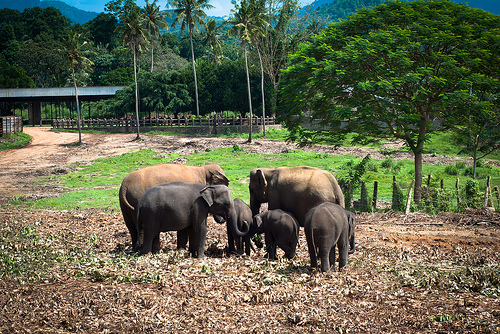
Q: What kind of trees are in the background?
A: Palm.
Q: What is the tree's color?
A: Green.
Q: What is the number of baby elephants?
A: Three.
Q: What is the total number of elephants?
A: Six.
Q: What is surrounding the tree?
A: Fence.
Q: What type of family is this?
A: Elephant.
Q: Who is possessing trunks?
A: Elephants.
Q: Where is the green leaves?
A: `On tree.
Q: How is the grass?
A: Dry.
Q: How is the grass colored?
A: Green.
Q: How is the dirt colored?
A: Brown.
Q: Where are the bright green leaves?
A: On tree.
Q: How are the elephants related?
A: Family.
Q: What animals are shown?
A: Elephant.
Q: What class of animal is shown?
A: Mammal.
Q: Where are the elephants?
A: On dirt.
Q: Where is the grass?
A: Behind the elephants.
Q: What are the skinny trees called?
A: Palm tree.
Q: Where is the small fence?
A: Around the nearest tree.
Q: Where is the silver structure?
A: Down the path.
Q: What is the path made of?
A: Dirt.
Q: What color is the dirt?
A: Brown.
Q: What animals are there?
A: Elephants.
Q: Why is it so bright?
A: Sun light.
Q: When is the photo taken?
A: Day time.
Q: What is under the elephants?
A: Dirt.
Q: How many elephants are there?
A: Six.